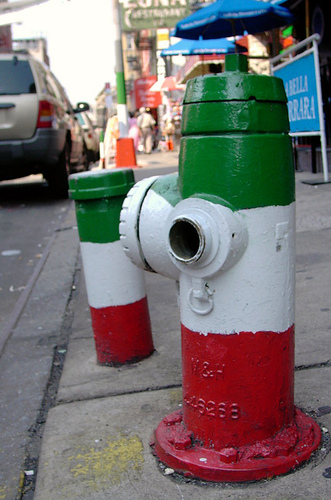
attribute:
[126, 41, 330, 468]
hydrant — red, green, white, italian flag themed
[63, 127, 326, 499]
sidewalk — concrete, cement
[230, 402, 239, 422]
number — 8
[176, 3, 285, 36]
umbrella — blue, white, closest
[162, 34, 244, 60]
umbrella — blue, white, red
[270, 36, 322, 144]
sign — blue, silver, white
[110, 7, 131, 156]
light pole — green, red, white, gray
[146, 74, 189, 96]
umbrella — white, red, striped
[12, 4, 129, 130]
sky — cloudy, white, bright, sunny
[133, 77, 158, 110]
sign — red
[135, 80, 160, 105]
letters — white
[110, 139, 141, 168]
block — orange, red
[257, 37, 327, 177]
frame — grey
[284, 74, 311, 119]
lettering — white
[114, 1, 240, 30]
sign — black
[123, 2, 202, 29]
letters — white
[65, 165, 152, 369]
pole — green, red, white, short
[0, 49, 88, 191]
vehicle — tan, big, beige, gold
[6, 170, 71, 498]
road — paved, black, cement